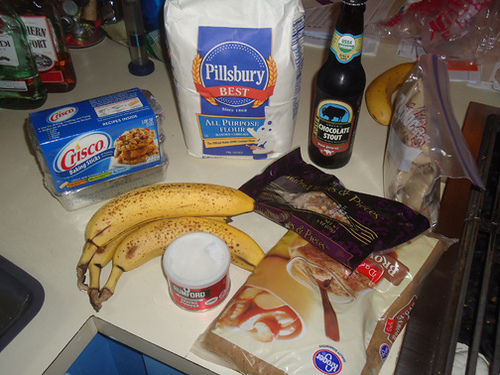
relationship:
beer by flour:
[304, 0, 370, 173] [172, 12, 292, 152]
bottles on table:
[1, 7, 84, 124] [13, 12, 432, 372]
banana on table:
[50, 151, 266, 228] [2, 119, 432, 371]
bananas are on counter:
[44, 187, 311, 319] [9, 110, 438, 363]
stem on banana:
[97, 266, 121, 302] [97, 215, 263, 302]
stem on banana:
[76, 240, 96, 291] [72, 183, 267, 310]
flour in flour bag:
[26, 227, 498, 357] [162, 0, 306, 162]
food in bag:
[275, 160, 389, 258] [271, 158, 394, 264]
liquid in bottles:
[30, 54, 76, 94] [16, 1, 78, 93]